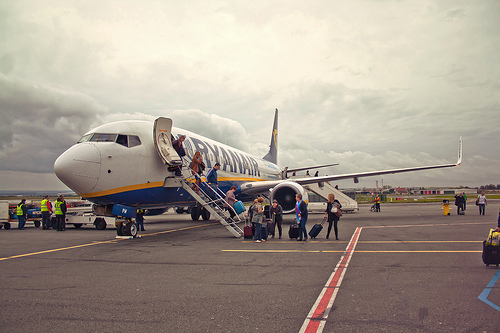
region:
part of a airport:
[399, 276, 423, 285]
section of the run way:
[226, 289, 243, 296]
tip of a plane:
[71, 146, 81, 172]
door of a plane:
[178, 129, 196, 156]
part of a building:
[433, 200, 442, 201]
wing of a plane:
[346, 172, 354, 178]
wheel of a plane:
[125, 216, 137, 240]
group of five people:
[257, 195, 282, 230]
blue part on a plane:
[131, 195, 135, 203]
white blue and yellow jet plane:
[53, 107, 462, 237]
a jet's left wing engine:
[270, 181, 308, 216]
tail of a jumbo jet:
[262, 107, 277, 164]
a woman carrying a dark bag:
[306, 192, 342, 238]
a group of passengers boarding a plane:
[240, 192, 340, 239]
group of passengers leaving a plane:
[171, 135, 246, 236]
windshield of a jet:
[79, 133, 141, 149]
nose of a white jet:
[52, 139, 102, 192]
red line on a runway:
[295, 235, 361, 331]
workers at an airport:
[17, 192, 68, 231]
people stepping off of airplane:
[148, 116, 347, 238]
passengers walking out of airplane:
[147, 110, 249, 244]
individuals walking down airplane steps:
[151, 108, 251, 240]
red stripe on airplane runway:
[278, 241, 369, 330]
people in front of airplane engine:
[241, 178, 348, 244]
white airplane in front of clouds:
[28, 58, 346, 178]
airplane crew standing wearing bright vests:
[5, 190, 69, 229]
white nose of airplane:
[47, 120, 105, 197]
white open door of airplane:
[147, 110, 191, 175]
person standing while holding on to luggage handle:
[307, 189, 347, 242]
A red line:
[274, 257, 339, 329]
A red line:
[307, 266, 349, 332]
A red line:
[288, 298, 326, 330]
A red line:
[272, 230, 366, 332]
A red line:
[298, 283, 328, 322]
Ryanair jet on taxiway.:
[51, 107, 464, 239]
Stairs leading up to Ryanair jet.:
[177, 157, 249, 239]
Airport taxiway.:
[0, 197, 499, 330]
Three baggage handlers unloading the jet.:
[15, 192, 67, 228]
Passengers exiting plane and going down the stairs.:
[168, 128, 245, 240]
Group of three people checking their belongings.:
[243, 194, 284, 242]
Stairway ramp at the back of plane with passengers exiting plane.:
[283, 167, 360, 216]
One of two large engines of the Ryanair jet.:
[268, 179, 310, 216]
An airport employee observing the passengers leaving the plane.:
[370, 193, 382, 212]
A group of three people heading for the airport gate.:
[453, 189, 487, 217]